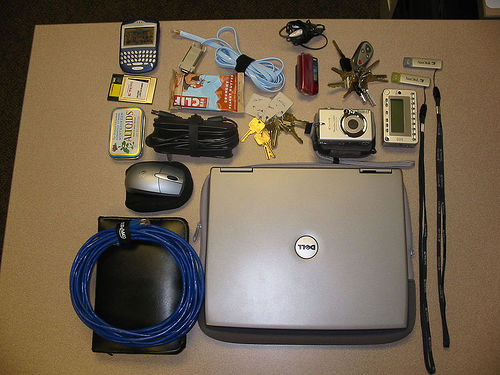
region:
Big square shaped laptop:
[209, 164, 406, 334]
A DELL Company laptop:
[290, 230, 331, 273]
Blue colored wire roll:
[160, 224, 199, 285]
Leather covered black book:
[104, 258, 171, 314]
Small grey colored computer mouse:
[121, 159, 191, 203]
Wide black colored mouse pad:
[126, 195, 180, 210]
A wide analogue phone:
[113, 14, 171, 77]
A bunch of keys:
[233, 105, 308, 160]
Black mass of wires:
[145, 107, 239, 164]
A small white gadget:
[381, 81, 421, 149]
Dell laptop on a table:
[184, 159, 433, 335]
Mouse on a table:
[128, 158, 190, 209]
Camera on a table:
[315, 103, 368, 150]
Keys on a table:
[340, 48, 379, 96]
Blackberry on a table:
[115, 17, 167, 84]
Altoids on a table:
[104, 105, 145, 157]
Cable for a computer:
[59, 199, 206, 349]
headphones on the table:
[281, 13, 326, 48]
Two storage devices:
[394, 49, 453, 100]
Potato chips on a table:
[166, 54, 242, 123]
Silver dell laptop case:
[199, 160, 415, 336]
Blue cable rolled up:
[66, 215, 208, 353]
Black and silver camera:
[310, 104, 375, 160]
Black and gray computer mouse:
[115, 160, 192, 201]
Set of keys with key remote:
[326, 33, 388, 100]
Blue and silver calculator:
[115, 16, 170, 72]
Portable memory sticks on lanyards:
[417, 55, 452, 370]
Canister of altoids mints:
[106, 106, 151, 161]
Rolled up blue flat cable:
[209, 24, 282, 86]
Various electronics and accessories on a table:
[56, 18, 464, 370]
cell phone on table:
[112, 20, 162, 70]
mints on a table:
[95, 102, 145, 157]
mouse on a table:
[121, 155, 192, 211]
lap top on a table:
[223, 163, 409, 353]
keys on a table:
[250, 90, 302, 153]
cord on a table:
[153, 103, 236, 165]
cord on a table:
[197, 20, 282, 72]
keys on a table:
[331, 31, 381, 101]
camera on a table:
[321, 102, 376, 165]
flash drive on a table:
[397, 53, 442, 86]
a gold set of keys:
[238, 93, 310, 160]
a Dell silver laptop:
[200, 155, 415, 340]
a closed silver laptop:
[200, 160, 415, 330]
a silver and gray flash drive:
[395, 50, 449, 70]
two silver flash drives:
[385, 50, 445, 85]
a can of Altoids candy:
[105, 95, 140, 155]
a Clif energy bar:
[165, 65, 250, 110]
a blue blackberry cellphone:
[110, 20, 170, 70]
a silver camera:
[310, 100, 375, 155]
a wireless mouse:
[115, 157, 195, 192]